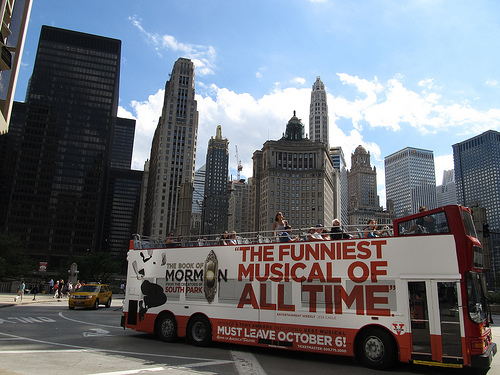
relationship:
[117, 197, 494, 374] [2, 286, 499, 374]
bus on road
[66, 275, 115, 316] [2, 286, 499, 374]
cab on road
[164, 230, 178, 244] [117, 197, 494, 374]
passenger on bus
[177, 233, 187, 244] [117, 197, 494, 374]
passenger on bus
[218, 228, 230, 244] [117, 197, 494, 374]
passenger on bus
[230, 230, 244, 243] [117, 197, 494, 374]
passenger on bus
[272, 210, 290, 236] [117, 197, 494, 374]
passenger on bus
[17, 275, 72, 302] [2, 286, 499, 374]
people walking on road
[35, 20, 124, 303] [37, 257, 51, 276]
building has advertisement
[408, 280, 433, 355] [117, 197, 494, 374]
door on bus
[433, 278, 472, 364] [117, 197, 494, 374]
door on bus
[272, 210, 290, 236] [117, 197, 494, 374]
passenger on top of bus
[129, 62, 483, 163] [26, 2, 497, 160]
clouds are in sky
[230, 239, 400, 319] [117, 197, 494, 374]
words are on bus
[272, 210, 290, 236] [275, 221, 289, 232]
passenger wearing shirt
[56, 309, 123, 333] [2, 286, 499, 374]
lines are on road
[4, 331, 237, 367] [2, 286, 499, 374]
lines are on road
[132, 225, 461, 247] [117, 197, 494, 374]
floor on bus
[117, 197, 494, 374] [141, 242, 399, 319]
bus has advertisement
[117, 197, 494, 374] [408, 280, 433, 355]
bus has door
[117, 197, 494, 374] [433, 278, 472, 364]
bus has door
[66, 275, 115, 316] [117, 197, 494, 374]
cab behind bus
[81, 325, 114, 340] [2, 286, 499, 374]
arrow on road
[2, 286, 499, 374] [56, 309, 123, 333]
road has lines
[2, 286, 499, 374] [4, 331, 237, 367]
road has lines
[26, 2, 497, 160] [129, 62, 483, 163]
sky has clouds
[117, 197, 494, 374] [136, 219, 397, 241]
bus has railing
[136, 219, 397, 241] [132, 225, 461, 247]
railing on floor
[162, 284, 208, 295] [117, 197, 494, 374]
words are on bus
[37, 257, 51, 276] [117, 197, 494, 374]
advertisement on bus